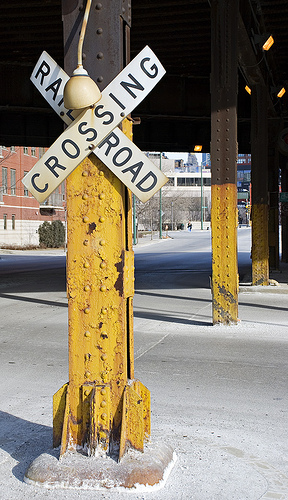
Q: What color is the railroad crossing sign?
A: White.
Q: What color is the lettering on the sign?
A: Black.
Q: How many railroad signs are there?
A: One.